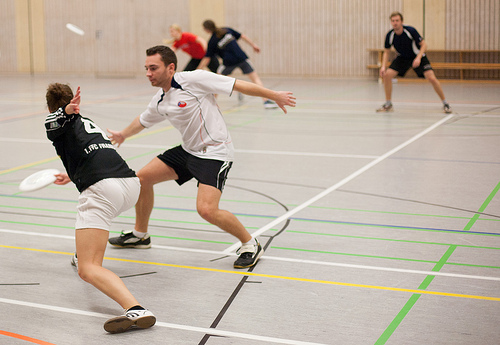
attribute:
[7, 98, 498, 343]
painted lines — different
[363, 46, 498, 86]
bleachers — Wooden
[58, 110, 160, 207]
shirt — white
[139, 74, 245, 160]
shirt — black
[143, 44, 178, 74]
hair — black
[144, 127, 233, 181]
sides —  his 